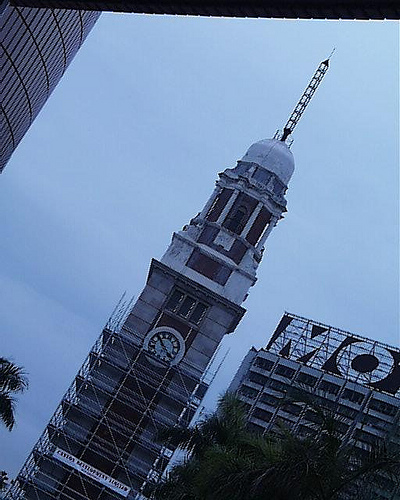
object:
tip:
[280, 44, 337, 141]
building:
[0, 44, 336, 500]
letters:
[263, 309, 400, 396]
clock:
[139, 322, 188, 371]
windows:
[164, 287, 211, 328]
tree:
[149, 376, 390, 500]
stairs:
[14, 314, 208, 499]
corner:
[238, 339, 271, 370]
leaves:
[157, 384, 400, 499]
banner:
[49, 446, 145, 500]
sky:
[0, 6, 398, 346]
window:
[250, 355, 274, 374]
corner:
[272, 305, 297, 328]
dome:
[237, 131, 303, 186]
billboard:
[266, 307, 399, 390]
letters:
[51, 445, 132, 498]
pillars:
[214, 184, 265, 241]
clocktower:
[0, 46, 336, 500]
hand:
[157, 335, 167, 350]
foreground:
[0, 399, 399, 498]